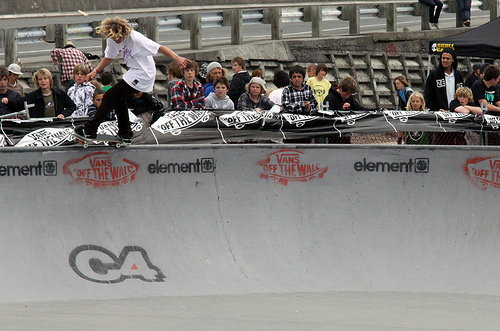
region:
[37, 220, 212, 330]
c4 written on the ramp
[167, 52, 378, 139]
people watching the skaters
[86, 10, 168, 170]
man doing tricks on ramp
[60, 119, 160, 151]
a skate board the man is riding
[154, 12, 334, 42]
guard rail on road behing the people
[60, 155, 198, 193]
advertisements painted on ramp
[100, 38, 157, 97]
the skater is wearing a white shirt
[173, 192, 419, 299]
concrete ramp for skating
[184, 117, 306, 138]
a banner behind ramp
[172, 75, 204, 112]
the boy wears a flannel shirt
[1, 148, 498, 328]
Gray ramp has graffiti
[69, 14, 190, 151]
Skateboarder is riding the edge of the ramp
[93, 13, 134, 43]
Skateboarder has curly dirty blonde hair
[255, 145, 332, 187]
Vans off the wall is the sponsor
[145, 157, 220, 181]
Element is the brand name on the ramp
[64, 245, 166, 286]
C4 is the name of the ramp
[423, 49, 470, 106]
Boy has on black, unzipped hoodie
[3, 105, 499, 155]
Vans off the wall tarp lines the fence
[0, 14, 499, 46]
Paved road in background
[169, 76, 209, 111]
Young boy has on black and red plaid shirt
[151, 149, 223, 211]
This skatepark has the word "element"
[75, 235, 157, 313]
This says C4 on it and is great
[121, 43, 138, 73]
This boy has a white t-shirt he is wearing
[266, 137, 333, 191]
The phrase here says "Vans off the Wall"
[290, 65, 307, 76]
There is a dark head of hair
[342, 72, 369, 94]
The color of this guy's hair is brown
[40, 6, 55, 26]
There is a silver girder for the road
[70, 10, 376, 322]
This photo was taken by Jackson Mingus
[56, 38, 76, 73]
This boy has a flannel shirt here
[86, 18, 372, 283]
This photo was taken in the early afternoon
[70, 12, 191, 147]
Blond male riding a skateboard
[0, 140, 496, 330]
Concrete skateboard wall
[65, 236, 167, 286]
Large C4 painted on the concrete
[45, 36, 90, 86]
Man in plaid shirt facing the road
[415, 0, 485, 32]
Two sets of legs in the upper right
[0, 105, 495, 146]
Black banner with white decals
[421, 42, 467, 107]
Adult with white shirt and black jacket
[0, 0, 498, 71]
Road barrier behind the skateboarder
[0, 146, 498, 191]
Strip of black and red logos on the wall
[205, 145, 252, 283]
Large crack in the cement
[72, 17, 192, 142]
A man with shaggy blonde and brown hair in black pants skateboarding.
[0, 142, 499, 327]
A grey skateboard ramp.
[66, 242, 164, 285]
Black outline of C4.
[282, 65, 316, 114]
A black haired boy in a black and white plaid shirt.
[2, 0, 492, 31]
A silver guard rail up by the road.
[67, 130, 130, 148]
A black and white skateboard.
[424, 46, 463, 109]
A man standing up with a black hooded coat on and white under shirt.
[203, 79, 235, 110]
A brown haired boy sitting down in a grey sweatshirt.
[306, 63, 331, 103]
A dark haired boy in a yellow shirt.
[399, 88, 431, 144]
A blonde haired girl with a green shirt on.